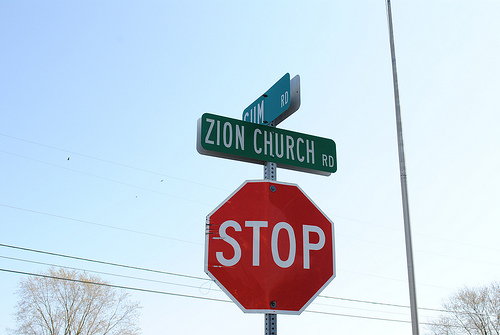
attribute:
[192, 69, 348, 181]
sign — green, greeny, whtie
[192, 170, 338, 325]
sign — whtie, red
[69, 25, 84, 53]
sky — blue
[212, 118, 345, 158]
letters — white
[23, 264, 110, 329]
tree — brown